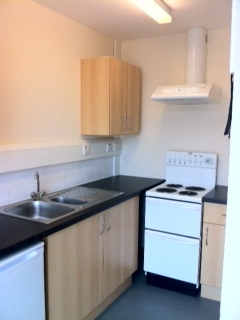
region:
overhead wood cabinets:
[80, 51, 142, 140]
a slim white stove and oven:
[144, 145, 213, 301]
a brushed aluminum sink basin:
[1, 170, 122, 227]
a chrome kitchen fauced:
[26, 169, 47, 202]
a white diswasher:
[1, 235, 48, 317]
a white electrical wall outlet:
[82, 144, 90, 157]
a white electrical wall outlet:
[105, 141, 112, 153]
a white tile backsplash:
[0, 152, 117, 205]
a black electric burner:
[154, 185, 175, 193]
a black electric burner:
[179, 189, 196, 196]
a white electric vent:
[150, 80, 219, 104]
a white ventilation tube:
[182, 26, 209, 83]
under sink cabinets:
[42, 201, 143, 319]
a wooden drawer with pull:
[201, 199, 228, 226]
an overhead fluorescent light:
[131, 0, 175, 30]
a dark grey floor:
[95, 276, 220, 318]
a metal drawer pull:
[96, 213, 104, 236]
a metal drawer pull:
[105, 210, 111, 232]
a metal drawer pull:
[202, 225, 208, 245]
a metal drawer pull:
[121, 113, 126, 131]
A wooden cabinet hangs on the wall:
[73, 50, 147, 142]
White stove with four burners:
[149, 155, 204, 278]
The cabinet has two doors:
[56, 198, 138, 319]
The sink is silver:
[2, 174, 86, 224]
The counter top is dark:
[101, 175, 152, 201]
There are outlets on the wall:
[78, 138, 123, 158]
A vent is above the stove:
[146, 70, 224, 115]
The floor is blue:
[126, 291, 156, 319]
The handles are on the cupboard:
[96, 213, 116, 232]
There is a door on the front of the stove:
[144, 201, 196, 273]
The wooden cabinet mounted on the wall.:
[78, 59, 151, 139]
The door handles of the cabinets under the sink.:
[94, 212, 119, 232]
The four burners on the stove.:
[162, 177, 202, 197]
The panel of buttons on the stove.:
[167, 149, 218, 167]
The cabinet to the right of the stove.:
[205, 199, 227, 304]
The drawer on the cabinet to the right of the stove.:
[205, 201, 226, 221]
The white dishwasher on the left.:
[2, 240, 44, 319]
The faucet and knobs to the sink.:
[27, 171, 44, 198]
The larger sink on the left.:
[5, 202, 76, 218]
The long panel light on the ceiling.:
[135, 1, 173, 26]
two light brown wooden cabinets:
[74, 53, 145, 143]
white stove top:
[147, 150, 222, 206]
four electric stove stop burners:
[154, 181, 207, 205]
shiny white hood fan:
[146, 25, 224, 110]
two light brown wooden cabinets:
[28, 197, 139, 319]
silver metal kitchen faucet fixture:
[28, 168, 49, 200]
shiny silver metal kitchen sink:
[1, 183, 123, 231]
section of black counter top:
[84, 165, 163, 202]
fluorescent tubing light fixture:
[126, 1, 177, 30]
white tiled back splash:
[0, 150, 126, 210]